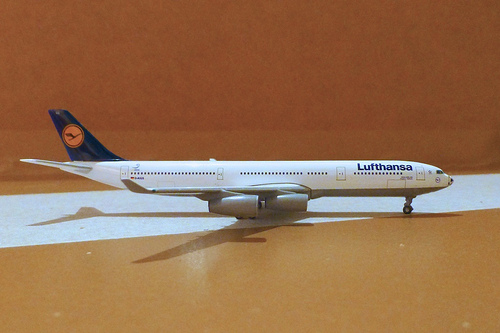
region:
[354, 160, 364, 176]
The letter is blue.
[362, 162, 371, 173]
The letter is blue.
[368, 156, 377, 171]
The letter is blue.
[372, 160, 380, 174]
The letter is blue.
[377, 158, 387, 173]
The letter is blue.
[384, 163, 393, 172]
The letter is blue.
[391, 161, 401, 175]
The letter is blue.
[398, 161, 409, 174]
The letter is blue.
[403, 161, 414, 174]
The letter is blue.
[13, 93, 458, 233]
The plane is white, blue and orange.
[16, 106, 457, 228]
Aircraft toy on the ground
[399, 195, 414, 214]
nose landing gear of the aircraft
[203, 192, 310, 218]
Engines of the aircraft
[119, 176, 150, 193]
Wing tip of the aircraft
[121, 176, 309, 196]
wing of the aircraft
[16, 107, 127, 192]
Tail section of the aircraft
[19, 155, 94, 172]
Elevators of the aircraft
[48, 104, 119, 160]
Rudder of the aircraft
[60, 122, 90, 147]
Airline logo on the aircraft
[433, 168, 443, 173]
cockpit window of the aircraft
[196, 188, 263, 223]
a white plane's engine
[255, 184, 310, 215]
a white plane's engine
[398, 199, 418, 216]
a white plane's tire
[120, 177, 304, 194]
a white plane's wing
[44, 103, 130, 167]
the blue tail of a plane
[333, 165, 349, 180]
a door on a plane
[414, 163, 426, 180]
a door on a plane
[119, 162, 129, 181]
a door on a plane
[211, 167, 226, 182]
a door on a plane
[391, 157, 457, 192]
a cockpit on a plane